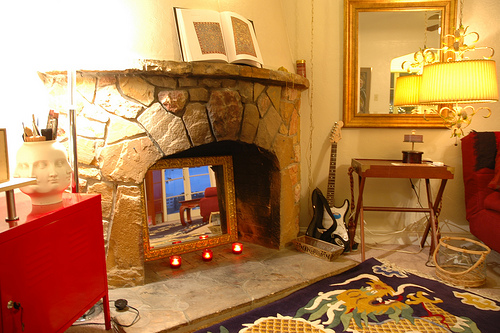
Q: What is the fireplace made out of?
A: Stone.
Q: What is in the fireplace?
A: Mirror.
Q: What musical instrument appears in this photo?
A: Electric guitar.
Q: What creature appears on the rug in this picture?
A: Dragon.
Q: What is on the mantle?
A: Book.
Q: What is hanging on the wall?
A: Mirror.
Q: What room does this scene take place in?
A: Living room.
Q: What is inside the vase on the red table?
A: Paint brushes.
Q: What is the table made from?
A: Wood.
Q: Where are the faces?
A: On vase.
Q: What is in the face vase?
A: Paint brushes.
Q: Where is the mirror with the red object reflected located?
A: Inside chimney.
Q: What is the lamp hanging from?
A: Chain.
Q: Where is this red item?
A: Next to chimney.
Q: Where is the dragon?
A: Rug.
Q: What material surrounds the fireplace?
A: Stone.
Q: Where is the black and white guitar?
A: Right of fireplace.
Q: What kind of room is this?
A: Living room.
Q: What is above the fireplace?
A: Large book.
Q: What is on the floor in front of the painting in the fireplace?
A: Tea lights.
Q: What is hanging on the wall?
A: Mirror.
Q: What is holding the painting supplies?
A: White face motif vase.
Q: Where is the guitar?
A: To the right of the fireplace.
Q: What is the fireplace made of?
A: Stones.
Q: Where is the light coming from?
A: Lamp on the right.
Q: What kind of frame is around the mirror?
A: Gold.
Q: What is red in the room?
A: A stand.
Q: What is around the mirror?
A: A gold frame.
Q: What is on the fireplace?
A: An open book.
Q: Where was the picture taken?
A: In a living room.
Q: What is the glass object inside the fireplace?
A: A mirror.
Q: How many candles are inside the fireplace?
A: Three.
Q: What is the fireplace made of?
A: Stone.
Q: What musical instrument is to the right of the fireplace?
A: A guitar.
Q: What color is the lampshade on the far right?
A: Yellow.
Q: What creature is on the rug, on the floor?
A: A dragon.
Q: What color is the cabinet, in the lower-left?
A: Red.